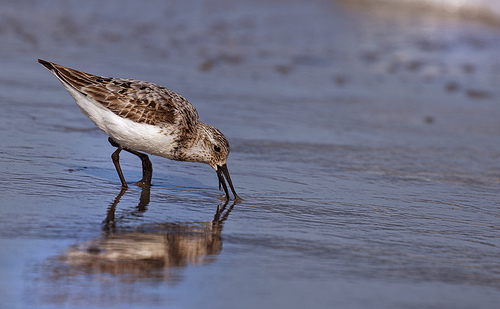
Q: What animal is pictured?
A: Bird.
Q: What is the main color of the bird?
A: Brown and white.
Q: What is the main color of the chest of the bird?
A: White.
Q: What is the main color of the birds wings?
A: Brown.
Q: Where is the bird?
A: On the wet sad.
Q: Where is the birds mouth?
A: In the water.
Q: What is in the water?
A: Reflection.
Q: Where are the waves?
A: In water.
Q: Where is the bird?
A: On beach.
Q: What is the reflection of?
A: Bird.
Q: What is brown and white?
A: Bird.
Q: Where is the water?
A: On ground.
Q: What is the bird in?
A: Water.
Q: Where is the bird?
A: On sand.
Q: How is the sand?
A: Wet.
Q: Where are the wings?
A: On bird.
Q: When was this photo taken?
A: Daytime.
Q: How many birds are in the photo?
A: One.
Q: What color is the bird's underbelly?
A: White.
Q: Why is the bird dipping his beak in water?
A: Thirsty.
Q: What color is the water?
A: Blue.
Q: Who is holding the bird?
A: No one.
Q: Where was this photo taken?
A: Near water.